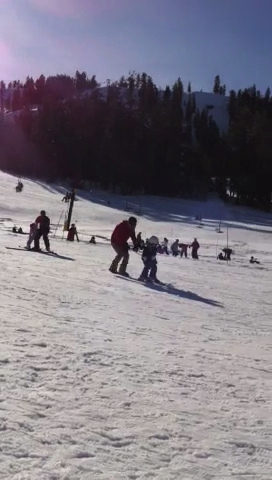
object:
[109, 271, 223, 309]
shadows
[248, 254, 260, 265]
person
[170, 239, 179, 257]
person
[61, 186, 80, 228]
pole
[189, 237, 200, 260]
person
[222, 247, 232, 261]
person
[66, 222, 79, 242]
person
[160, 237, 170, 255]
person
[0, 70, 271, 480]
hillside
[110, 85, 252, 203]
building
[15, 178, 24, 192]
chairlift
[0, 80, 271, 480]
snow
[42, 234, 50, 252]
leg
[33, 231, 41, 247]
leg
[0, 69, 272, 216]
trees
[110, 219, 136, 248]
jacket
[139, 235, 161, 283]
child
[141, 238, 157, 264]
coat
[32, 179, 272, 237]
shadow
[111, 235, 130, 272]
brown pants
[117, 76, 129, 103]
chimney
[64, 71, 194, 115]
roof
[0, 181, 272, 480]
ground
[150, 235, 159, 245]
hat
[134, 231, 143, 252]
person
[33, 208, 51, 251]
man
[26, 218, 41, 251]
child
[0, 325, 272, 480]
footprints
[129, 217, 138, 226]
hat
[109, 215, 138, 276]
adult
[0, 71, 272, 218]
hill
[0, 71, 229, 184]
rock formation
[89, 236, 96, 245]
object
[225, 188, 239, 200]
lights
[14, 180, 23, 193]
people